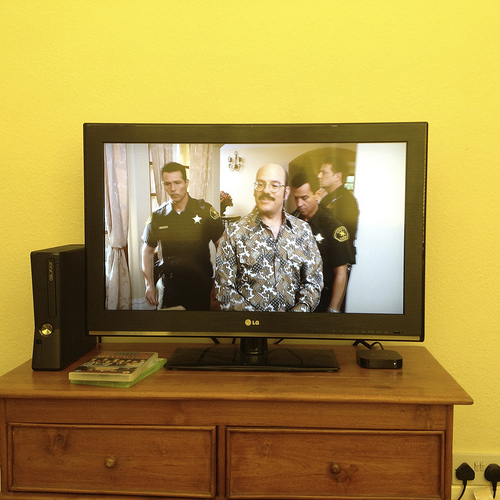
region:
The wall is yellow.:
[112, 38, 413, 95]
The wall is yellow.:
[154, 45, 295, 149]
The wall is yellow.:
[261, 24, 359, 81]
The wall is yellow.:
[147, 30, 264, 105]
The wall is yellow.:
[117, 45, 247, 125]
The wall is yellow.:
[160, 8, 255, 79]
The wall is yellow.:
[71, 22, 293, 112]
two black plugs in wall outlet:
[452, 450, 499, 490]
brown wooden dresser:
[8, 335, 467, 493]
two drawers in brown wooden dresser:
[8, 420, 443, 494]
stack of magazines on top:
[83, 350, 154, 386]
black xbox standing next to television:
[35, 240, 91, 362]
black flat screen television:
[83, 125, 422, 340]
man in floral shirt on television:
[228, 162, 312, 307]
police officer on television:
[151, 167, 211, 303]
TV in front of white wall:
[0, 0, 497, 357]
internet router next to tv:
[353, 350, 395, 368]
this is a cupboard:
[21, 380, 426, 497]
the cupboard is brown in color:
[193, 374, 290, 398]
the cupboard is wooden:
[183, 370, 273, 395]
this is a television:
[91, 125, 404, 320]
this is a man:
[231, 167, 311, 304]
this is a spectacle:
[247, 179, 284, 190]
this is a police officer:
[145, 167, 202, 312]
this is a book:
[84, 354, 129, 376]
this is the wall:
[171, 27, 456, 108]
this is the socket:
[455, 452, 498, 484]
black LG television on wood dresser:
[77, 118, 431, 382]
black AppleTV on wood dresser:
[344, 336, 411, 383]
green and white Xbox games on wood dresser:
[61, 346, 169, 395]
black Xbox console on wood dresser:
[28, 241, 94, 374]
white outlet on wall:
[450, 449, 498, 493]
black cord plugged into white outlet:
[451, 462, 474, 499]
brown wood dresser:
[2, 339, 474, 496]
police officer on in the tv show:
[142, 159, 224, 313]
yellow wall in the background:
[2, 0, 495, 381]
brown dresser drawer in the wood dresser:
[2, 416, 217, 499]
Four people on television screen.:
[118, 148, 376, 313]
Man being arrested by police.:
[214, 160, 326, 310]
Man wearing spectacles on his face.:
[216, 159, 322, 311]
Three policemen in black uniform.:
[147, 152, 380, 313]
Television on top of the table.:
[80, 116, 427, 380]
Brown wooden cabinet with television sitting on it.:
[1, 328, 494, 494]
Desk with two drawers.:
[2, 340, 474, 498]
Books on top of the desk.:
[63, 335, 168, 389]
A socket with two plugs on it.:
[449, 445, 493, 498]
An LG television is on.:
[82, 116, 442, 376]